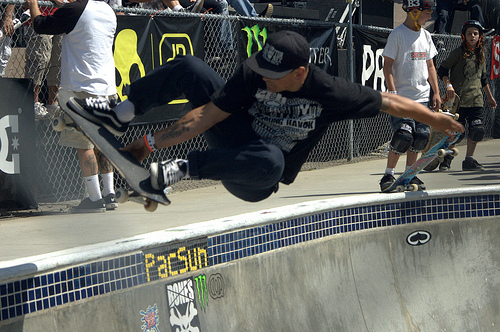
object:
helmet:
[402, 0, 438, 12]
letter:
[145, 246, 208, 282]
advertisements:
[112, 15, 203, 125]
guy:
[27, 1, 118, 212]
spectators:
[0, 0, 274, 120]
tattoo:
[158, 116, 196, 142]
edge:
[0, 185, 500, 282]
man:
[68, 31, 466, 203]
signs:
[353, 26, 389, 92]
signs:
[262, 42, 284, 65]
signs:
[490, 35, 499, 80]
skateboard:
[52, 87, 172, 212]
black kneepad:
[390, 128, 414, 153]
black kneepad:
[412, 132, 429, 150]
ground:
[0, 208, 126, 263]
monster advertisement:
[140, 274, 209, 331]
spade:
[406, 229, 432, 245]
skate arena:
[0, 139, 500, 332]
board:
[56, 87, 171, 207]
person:
[380, 1, 443, 191]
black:
[175, 302, 188, 316]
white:
[112, 99, 135, 123]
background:
[0, 0, 500, 204]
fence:
[0, 0, 500, 206]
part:
[262, 250, 333, 319]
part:
[278, 249, 378, 319]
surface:
[0, 194, 500, 332]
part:
[273, 259, 363, 308]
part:
[94, 154, 158, 184]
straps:
[408, 10, 422, 31]